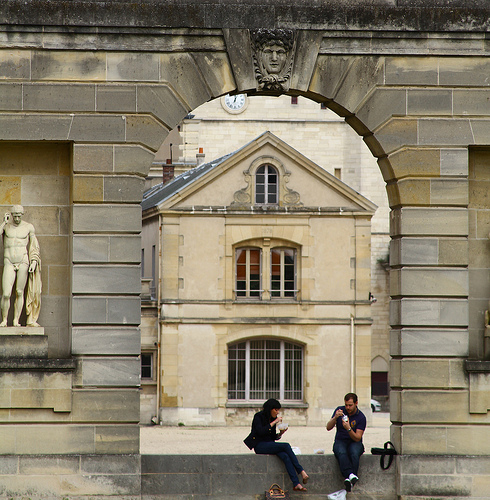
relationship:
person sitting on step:
[243, 395, 312, 492] [143, 449, 394, 496]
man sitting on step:
[327, 393, 367, 491] [143, 449, 394, 496]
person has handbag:
[243, 398, 309, 492] [255, 482, 288, 498]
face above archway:
[249, 23, 291, 87] [134, 86, 412, 491]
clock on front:
[215, 95, 253, 118] [145, 90, 376, 430]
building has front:
[139, 90, 392, 430] [145, 90, 376, 430]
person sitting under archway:
[243, 395, 312, 492] [134, 86, 412, 491]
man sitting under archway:
[327, 393, 367, 491] [134, 86, 412, 491]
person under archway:
[243, 395, 312, 492] [134, 86, 412, 491]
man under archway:
[327, 393, 367, 491] [134, 86, 412, 491]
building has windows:
[139, 90, 392, 430] [229, 159, 313, 398]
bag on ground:
[369, 439, 403, 473] [137, 424, 393, 497]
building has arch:
[139, 90, 392, 430] [140, 130, 379, 209]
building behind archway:
[139, 90, 392, 430] [134, 86, 412, 491]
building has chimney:
[139, 90, 392, 430] [160, 140, 178, 184]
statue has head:
[1, 204, 50, 325] [6, 206, 27, 227]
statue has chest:
[1, 204, 50, 325] [5, 226, 26, 263]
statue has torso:
[1, 204, 50, 325] [5, 227, 26, 264]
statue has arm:
[1, 204, 50, 325] [29, 231, 40, 263]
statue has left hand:
[1, 204, 50, 325] [3, 211, 15, 227]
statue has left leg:
[1, 204, 50, 325] [13, 267, 27, 328]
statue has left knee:
[1, 204, 50, 325] [14, 283, 29, 297]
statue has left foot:
[1, 204, 50, 325] [13, 318, 23, 330]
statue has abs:
[1, 204, 50, 325] [6, 241, 28, 255]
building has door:
[139, 90, 392, 430] [372, 353, 388, 406]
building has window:
[139, 90, 392, 430] [227, 340, 312, 400]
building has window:
[139, 90, 392, 430] [232, 243, 300, 290]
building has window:
[139, 90, 392, 430] [253, 163, 279, 199]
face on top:
[249, 23, 291, 87] [161, 1, 369, 115]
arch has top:
[140, 85, 405, 210] [161, 1, 369, 115]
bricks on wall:
[5, 61, 485, 498] [4, 1, 489, 493]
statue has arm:
[1, 204, 50, 325] [26, 223, 42, 271]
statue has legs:
[1, 204, 50, 325] [3, 260, 28, 324]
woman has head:
[264, 398, 284, 421] [6, 206, 27, 227]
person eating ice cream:
[243, 395, 312, 492] [272, 412, 287, 432]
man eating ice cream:
[327, 393, 367, 491] [338, 410, 350, 423]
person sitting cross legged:
[243, 398, 309, 492] [256, 443, 313, 488]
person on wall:
[243, 398, 309, 492] [4, 1, 489, 493]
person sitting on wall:
[243, 398, 309, 492] [142, 452, 401, 497]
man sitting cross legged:
[329, 394, 371, 489] [334, 440, 363, 480]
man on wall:
[329, 394, 371, 489] [142, 452, 401, 497]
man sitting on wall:
[329, 394, 371, 489] [142, 452, 401, 497]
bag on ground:
[323, 486, 346, 498] [137, 424, 393, 497]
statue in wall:
[1, 204, 50, 325] [4, 1, 489, 493]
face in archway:
[249, 23, 291, 87] [134, 86, 412, 491]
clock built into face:
[215, 95, 253, 118] [143, 89, 392, 430]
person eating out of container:
[243, 398, 309, 492] [273, 420, 289, 431]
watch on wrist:
[346, 427, 355, 435] [346, 423, 352, 431]